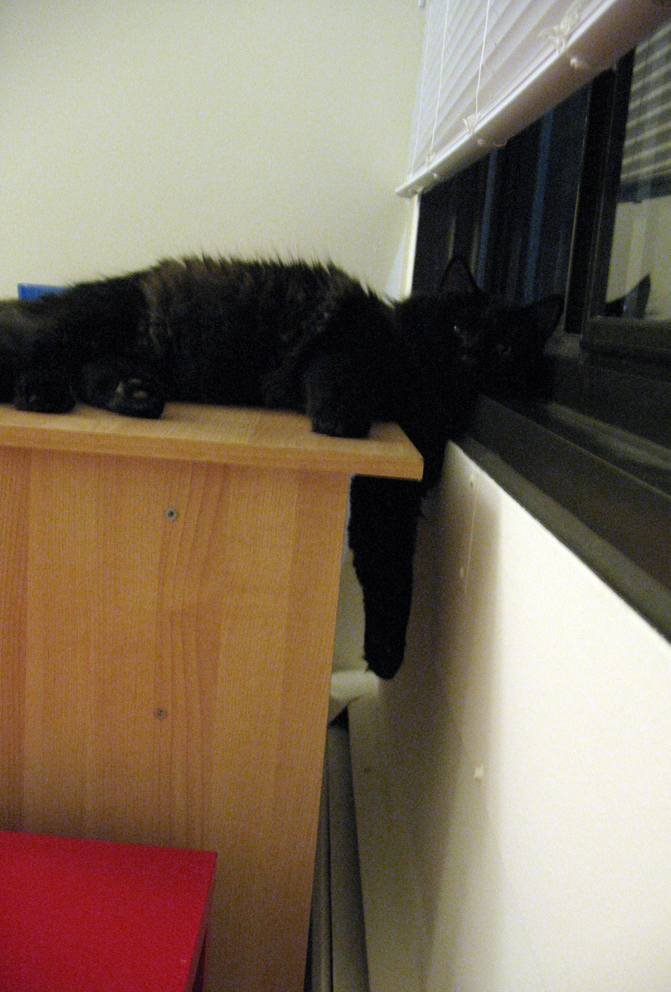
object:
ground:
[605, 196, 671, 319]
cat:
[0, 250, 567, 699]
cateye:
[453, 327, 458, 333]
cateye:
[497, 344, 511, 357]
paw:
[308, 396, 373, 439]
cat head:
[428, 247, 566, 409]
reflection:
[604, 274, 652, 316]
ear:
[438, 252, 479, 298]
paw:
[14, 368, 76, 415]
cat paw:
[347, 476, 423, 679]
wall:
[377, 439, 671, 991]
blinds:
[393, 0, 670, 197]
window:
[392, 0, 668, 643]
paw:
[114, 378, 166, 419]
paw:
[363, 636, 404, 681]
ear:
[525, 291, 565, 344]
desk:
[0, 400, 425, 992]